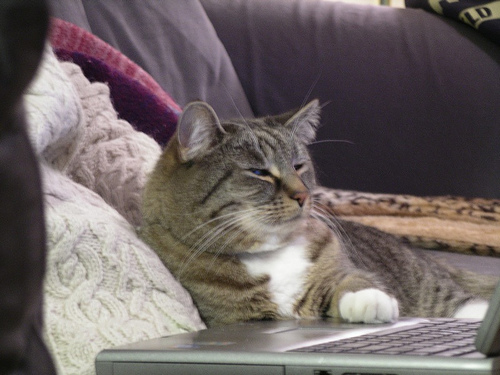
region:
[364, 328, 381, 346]
edge of a laptop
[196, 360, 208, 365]
part of a laptop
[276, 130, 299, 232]
nose of a cat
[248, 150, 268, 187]
eye of a cat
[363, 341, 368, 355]
part of a key board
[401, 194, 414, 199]
part of a matress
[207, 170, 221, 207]
ear of a cat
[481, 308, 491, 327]
part of a screen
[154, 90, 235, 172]
White ear of a cat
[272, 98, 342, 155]
White ear of a cat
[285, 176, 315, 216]
Pink nose of a cat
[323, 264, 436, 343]
White paw of a cat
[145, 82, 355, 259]
Small cat glairing at me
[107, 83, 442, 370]
Small cat doing work on MTURK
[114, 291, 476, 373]
Small wilver laptop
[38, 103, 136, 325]
White crochaet afaghan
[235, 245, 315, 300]
White fur on a cat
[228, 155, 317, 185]
The kittens eyes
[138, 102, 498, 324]
a cat resting on a couch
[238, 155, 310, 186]
a cat with its eyes half closed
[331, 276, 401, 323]
a cat with its paw on a laptop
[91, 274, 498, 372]
a silvery laptop on a couch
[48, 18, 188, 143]
a red blanket on a couch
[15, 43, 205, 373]
a white blanket on a couch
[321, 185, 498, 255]
a leopard printed blanket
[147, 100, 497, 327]
a tabby cat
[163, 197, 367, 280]
white mustaches of a cat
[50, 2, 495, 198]
a gray couch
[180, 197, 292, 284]
long white cat whiskers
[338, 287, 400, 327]
white cat paws on the laptop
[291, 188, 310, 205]
the cat has a pink nose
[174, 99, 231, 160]
the cats grey ears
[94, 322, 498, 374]
a silver color lap top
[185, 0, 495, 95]
a grey color sofa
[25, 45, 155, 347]
a white knit comforter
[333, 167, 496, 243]
a brown color afghan comforter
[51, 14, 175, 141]
a red and purple blanket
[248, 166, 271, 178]
the cats dark eye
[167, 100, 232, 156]
ear of a cat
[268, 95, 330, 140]
ear of a cat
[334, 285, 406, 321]
paw of a cat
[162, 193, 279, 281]
whiskers of a cat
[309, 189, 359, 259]
whiskers of a cat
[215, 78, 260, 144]
whisker of a cat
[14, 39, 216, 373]
white blanket behind a cat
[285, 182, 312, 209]
nose of a cat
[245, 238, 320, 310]
white chest of a cat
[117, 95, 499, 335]
cat on a couch